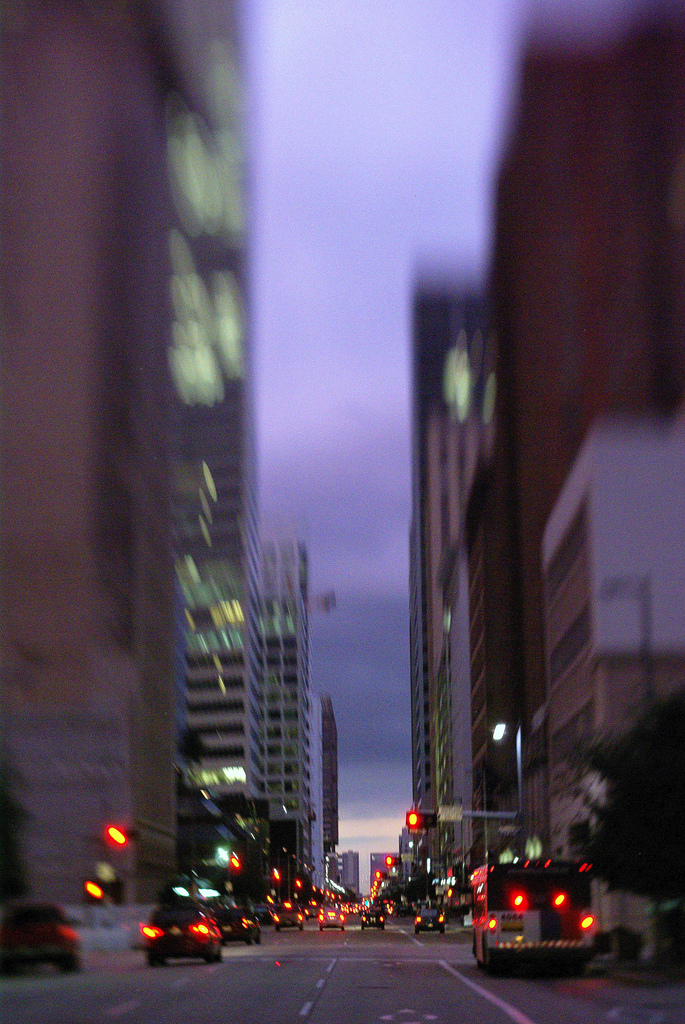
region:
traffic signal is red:
[401, 802, 424, 833]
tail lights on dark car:
[134, 895, 225, 966]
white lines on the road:
[11, 911, 683, 1017]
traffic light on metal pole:
[406, 717, 531, 842]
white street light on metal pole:
[402, 711, 531, 855]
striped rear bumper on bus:
[465, 855, 598, 965]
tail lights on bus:
[468, 852, 605, 971]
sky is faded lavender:
[239, 2, 530, 891]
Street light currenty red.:
[390, 790, 541, 834]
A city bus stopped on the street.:
[460, 851, 613, 984]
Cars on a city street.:
[23, 821, 621, 1015]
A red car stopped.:
[130, 893, 234, 974]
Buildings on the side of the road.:
[1, 2, 349, 910]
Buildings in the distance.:
[323, 844, 413, 919]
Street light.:
[474, 710, 554, 885]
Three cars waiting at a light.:
[266, 902, 399, 938]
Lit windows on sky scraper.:
[162, 124, 279, 907]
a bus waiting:
[473, 872, 608, 969]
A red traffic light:
[389, 798, 521, 833]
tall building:
[185, 691, 326, 826]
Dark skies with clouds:
[342, 702, 414, 846]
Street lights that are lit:
[320, 883, 361, 897]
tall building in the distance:
[341, 851, 368, 905]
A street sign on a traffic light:
[433, 806, 468, 821]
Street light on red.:
[80, 810, 241, 965]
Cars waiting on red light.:
[111, 858, 284, 981]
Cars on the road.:
[209, 877, 455, 944]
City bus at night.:
[453, 846, 616, 988]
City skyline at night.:
[1, 0, 361, 911]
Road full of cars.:
[118, 822, 571, 1023]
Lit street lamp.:
[467, 704, 572, 939]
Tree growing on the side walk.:
[564, 722, 678, 1008]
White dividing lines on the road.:
[275, 937, 343, 1021]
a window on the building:
[253, 710, 269, 731]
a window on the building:
[279, 741, 288, 766]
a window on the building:
[286, 778, 293, 804]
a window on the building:
[271, 741, 276, 761]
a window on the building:
[226, 723, 244, 742]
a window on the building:
[204, 703, 223, 723]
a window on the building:
[238, 684, 247, 701]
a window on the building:
[188, 638, 215, 661]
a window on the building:
[238, 565, 243, 597]